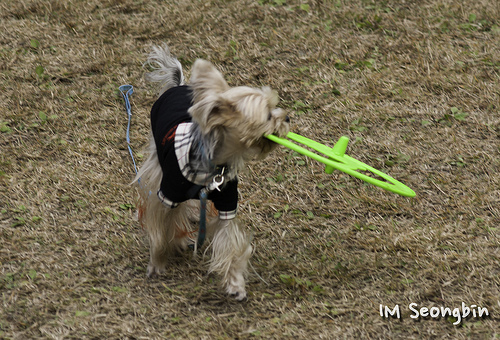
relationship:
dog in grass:
[129, 40, 292, 300] [1, 1, 499, 339]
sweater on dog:
[149, 84, 238, 220] [129, 40, 292, 300]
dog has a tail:
[129, 40, 292, 300] [146, 40, 183, 90]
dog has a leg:
[129, 40, 292, 300] [209, 195, 254, 303]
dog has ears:
[129, 40, 292, 300] [188, 97, 239, 136]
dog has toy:
[129, 40, 292, 300] [265, 128, 418, 200]